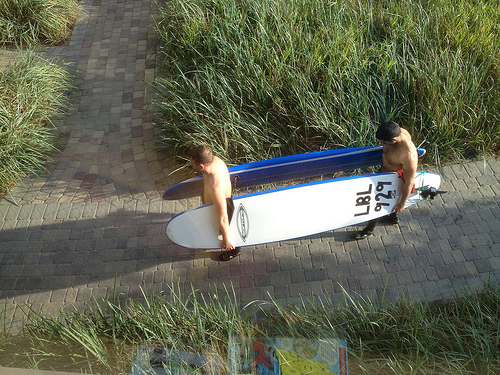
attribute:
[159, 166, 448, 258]
surfboards — long, large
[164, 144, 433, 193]
surfboard — large, long, blue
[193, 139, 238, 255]
man — white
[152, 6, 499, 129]
grass — tall, thick, green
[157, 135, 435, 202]
surfboard — blue, white